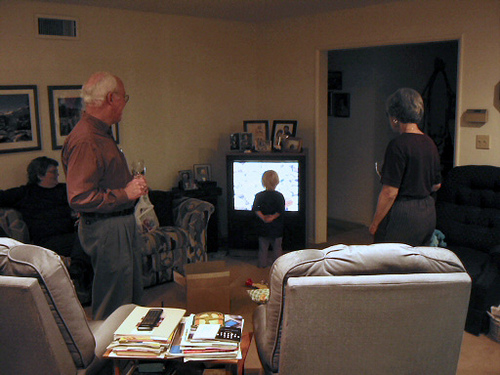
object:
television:
[226, 151, 307, 256]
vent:
[36, 17, 78, 38]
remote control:
[137, 309, 163, 331]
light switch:
[483, 140, 485, 143]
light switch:
[478, 140, 481, 143]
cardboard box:
[170, 260, 232, 314]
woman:
[369, 87, 443, 247]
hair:
[385, 87, 424, 123]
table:
[103, 328, 254, 374]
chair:
[433, 165, 500, 337]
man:
[59, 75, 150, 320]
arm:
[63, 137, 128, 212]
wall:
[0, 0, 253, 238]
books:
[185, 310, 243, 342]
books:
[112, 305, 187, 337]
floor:
[77, 237, 500, 374]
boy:
[252, 170, 286, 269]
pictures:
[243, 120, 269, 152]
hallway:
[327, 47, 373, 241]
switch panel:
[476, 135, 490, 150]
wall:
[254, 0, 498, 244]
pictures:
[193, 164, 211, 183]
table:
[172, 179, 223, 253]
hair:
[262, 170, 280, 190]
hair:
[79, 72, 118, 107]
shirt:
[381, 132, 442, 199]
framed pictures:
[271, 120, 298, 153]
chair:
[0, 237, 137, 374]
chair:
[251, 242, 472, 375]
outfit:
[373, 130, 441, 246]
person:
[0, 156, 94, 306]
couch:
[0, 190, 215, 306]